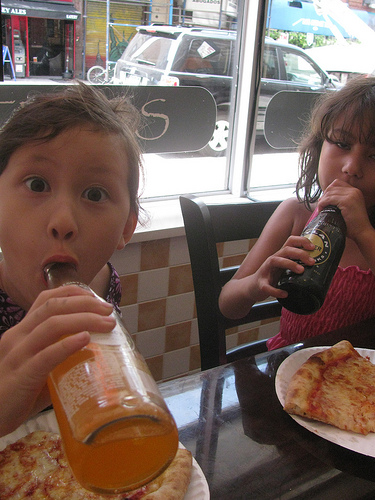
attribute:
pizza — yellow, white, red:
[283, 336, 374, 438]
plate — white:
[268, 333, 374, 457]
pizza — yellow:
[277, 336, 374, 451]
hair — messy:
[16, 81, 138, 151]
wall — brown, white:
[97, 234, 300, 385]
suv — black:
[106, 12, 350, 168]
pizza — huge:
[285, 343, 373, 435]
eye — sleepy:
[331, 139, 349, 152]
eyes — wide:
[17, 159, 122, 204]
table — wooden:
[163, 383, 374, 498]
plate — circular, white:
[274, 330, 372, 458]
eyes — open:
[13, 165, 108, 215]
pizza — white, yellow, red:
[294, 356, 374, 431]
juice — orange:
[42, 332, 180, 494]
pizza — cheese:
[222, 308, 373, 453]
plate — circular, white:
[1, 402, 213, 498]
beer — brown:
[273, 201, 346, 315]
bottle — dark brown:
[276, 190, 348, 311]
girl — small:
[1, 76, 141, 435]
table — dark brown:
[153, 318, 368, 496]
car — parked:
[108, 22, 345, 157]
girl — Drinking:
[295, 77, 374, 225]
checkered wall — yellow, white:
[106, 235, 281, 379]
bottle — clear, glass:
[42, 275, 184, 444]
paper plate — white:
[272, 345, 362, 456]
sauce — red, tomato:
[112, 474, 150, 498]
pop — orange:
[28, 244, 182, 494]